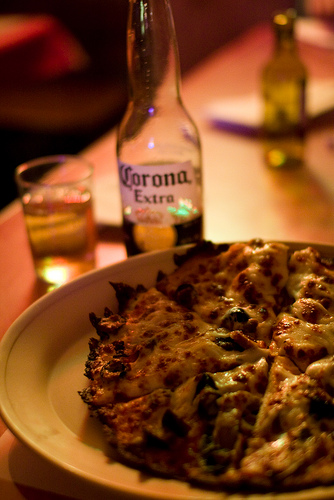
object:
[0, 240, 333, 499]
plate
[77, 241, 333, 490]
pizza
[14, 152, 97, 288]
cup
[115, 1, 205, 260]
bottle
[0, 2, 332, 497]
counter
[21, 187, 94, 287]
drink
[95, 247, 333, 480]
cheese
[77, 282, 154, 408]
crust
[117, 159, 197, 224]
label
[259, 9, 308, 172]
bottle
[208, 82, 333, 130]
object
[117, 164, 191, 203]
writing